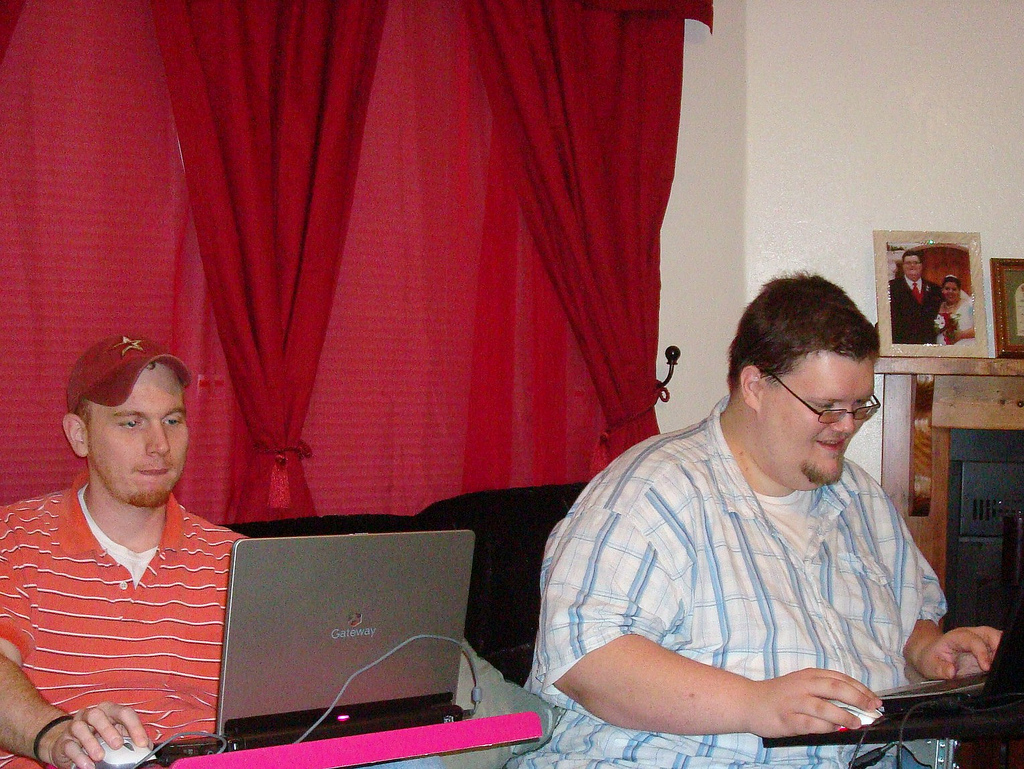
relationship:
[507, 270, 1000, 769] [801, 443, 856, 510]
man has beard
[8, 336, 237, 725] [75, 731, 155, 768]
man clicking mouse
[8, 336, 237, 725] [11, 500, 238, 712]
man wearing shirt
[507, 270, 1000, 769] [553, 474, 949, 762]
man wearing shirt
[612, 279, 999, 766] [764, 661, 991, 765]
man typing keyboard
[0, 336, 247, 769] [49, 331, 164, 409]
man wearing hat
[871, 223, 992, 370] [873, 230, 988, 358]
frame surrounding frame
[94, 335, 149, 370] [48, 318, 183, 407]
logo attached to hat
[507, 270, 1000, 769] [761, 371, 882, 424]
man wearing eyeglasses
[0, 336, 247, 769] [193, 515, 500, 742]
man working on computer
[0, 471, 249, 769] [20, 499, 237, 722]
polo are on polo